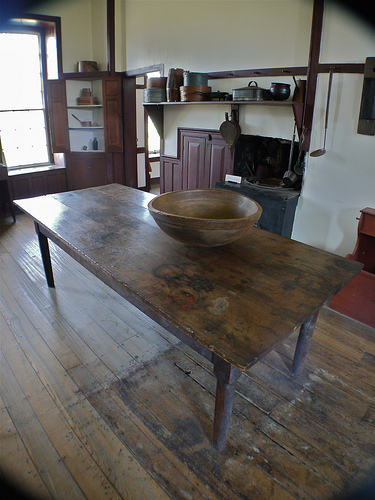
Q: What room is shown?
A: It is a kitchen.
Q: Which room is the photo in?
A: It is at the kitchen.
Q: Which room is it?
A: It is a kitchen.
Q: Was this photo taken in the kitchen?
A: Yes, it was taken in the kitchen.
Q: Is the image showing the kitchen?
A: Yes, it is showing the kitchen.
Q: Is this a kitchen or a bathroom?
A: It is a kitchen.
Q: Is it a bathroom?
A: No, it is a kitchen.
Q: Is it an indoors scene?
A: Yes, it is indoors.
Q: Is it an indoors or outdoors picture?
A: It is indoors.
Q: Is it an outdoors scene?
A: No, it is indoors.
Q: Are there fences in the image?
A: No, there are no fences.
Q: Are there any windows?
A: Yes, there is a window.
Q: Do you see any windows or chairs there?
A: Yes, there is a window.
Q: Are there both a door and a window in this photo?
A: Yes, there are both a window and a door.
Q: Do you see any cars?
A: No, there are no cars.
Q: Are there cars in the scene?
A: No, there are no cars.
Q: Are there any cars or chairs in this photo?
A: No, there are no cars or chairs.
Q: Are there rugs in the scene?
A: No, there are no rugs.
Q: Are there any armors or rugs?
A: No, there are no rugs or armors.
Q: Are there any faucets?
A: No, there are no faucets.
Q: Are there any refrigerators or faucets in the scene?
A: No, there are no faucets or refrigerators.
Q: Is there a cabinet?
A: Yes, there is a cabinet.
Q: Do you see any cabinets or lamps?
A: Yes, there is a cabinet.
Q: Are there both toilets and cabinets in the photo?
A: No, there is a cabinet but no toilets.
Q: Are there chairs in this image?
A: No, there are no chairs.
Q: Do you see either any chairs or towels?
A: No, there are no chairs or towels.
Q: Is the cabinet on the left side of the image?
A: Yes, the cabinet is on the left of the image.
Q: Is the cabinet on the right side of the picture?
A: No, the cabinet is on the left of the image.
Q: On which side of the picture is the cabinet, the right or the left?
A: The cabinet is on the left of the image.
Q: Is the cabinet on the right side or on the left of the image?
A: The cabinet is on the left of the image.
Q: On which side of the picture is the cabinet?
A: The cabinet is on the left of the image.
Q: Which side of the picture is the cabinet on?
A: The cabinet is on the left of the image.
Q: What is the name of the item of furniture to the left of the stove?
A: The piece of furniture is a cabinet.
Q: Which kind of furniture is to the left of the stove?
A: The piece of furniture is a cabinet.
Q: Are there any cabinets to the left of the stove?
A: Yes, there is a cabinet to the left of the stove.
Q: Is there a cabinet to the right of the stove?
A: No, the cabinet is to the left of the stove.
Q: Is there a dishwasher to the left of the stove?
A: No, there is a cabinet to the left of the stove.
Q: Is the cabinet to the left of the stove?
A: Yes, the cabinet is to the left of the stove.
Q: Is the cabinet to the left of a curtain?
A: No, the cabinet is to the left of the stove.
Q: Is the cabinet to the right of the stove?
A: No, the cabinet is to the left of the stove.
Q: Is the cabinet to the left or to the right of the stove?
A: The cabinet is to the left of the stove.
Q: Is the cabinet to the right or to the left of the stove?
A: The cabinet is to the left of the stove.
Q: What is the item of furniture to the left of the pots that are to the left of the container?
A: The piece of furniture is a cabinet.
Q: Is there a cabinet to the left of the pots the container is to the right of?
A: Yes, there is a cabinet to the left of the pots.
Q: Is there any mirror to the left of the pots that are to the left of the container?
A: No, there is a cabinet to the left of the pots.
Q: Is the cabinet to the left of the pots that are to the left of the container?
A: Yes, the cabinet is to the left of the pots.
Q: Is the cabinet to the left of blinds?
A: No, the cabinet is to the left of the pots.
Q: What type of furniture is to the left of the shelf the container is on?
A: The piece of furniture is a cabinet.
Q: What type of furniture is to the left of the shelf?
A: The piece of furniture is a cabinet.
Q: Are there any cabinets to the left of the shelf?
A: Yes, there is a cabinet to the left of the shelf.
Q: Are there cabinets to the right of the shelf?
A: No, the cabinet is to the left of the shelf.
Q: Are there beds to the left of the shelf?
A: No, there is a cabinet to the left of the shelf.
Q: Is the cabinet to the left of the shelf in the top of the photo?
A: Yes, the cabinet is to the left of the shelf.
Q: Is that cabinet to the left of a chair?
A: No, the cabinet is to the left of the shelf.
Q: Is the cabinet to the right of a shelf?
A: No, the cabinet is to the left of a shelf.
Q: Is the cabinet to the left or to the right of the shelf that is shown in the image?
A: The cabinet is to the left of the shelf.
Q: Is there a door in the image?
A: Yes, there are doors.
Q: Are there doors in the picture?
A: Yes, there are doors.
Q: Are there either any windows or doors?
A: Yes, there are doors.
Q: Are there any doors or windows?
A: Yes, there are doors.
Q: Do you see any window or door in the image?
A: Yes, there are doors.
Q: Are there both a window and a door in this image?
A: Yes, there are both a door and a window.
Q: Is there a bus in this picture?
A: No, there are no buses.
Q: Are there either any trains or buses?
A: No, there are no buses or trains.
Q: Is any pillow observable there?
A: No, there are no pillows.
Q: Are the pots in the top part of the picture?
A: Yes, the pots are in the top of the image.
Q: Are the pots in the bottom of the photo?
A: No, the pots are in the top of the image.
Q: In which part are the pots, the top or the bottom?
A: The pots are in the top of the image.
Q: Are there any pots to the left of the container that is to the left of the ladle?
A: Yes, there are pots to the left of the container.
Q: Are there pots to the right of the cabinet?
A: Yes, there are pots to the right of the cabinet.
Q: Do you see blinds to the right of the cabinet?
A: No, there are pots to the right of the cabinet.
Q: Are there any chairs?
A: No, there are no chairs.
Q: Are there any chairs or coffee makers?
A: No, there are no chairs or coffee makers.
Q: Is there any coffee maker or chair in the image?
A: No, there are no chairs or coffee makers.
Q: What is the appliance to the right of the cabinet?
A: The appliance is a stove.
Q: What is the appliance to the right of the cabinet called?
A: The appliance is a stove.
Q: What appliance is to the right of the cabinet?
A: The appliance is a stove.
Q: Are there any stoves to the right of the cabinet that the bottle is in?
A: Yes, there is a stove to the right of the cabinet.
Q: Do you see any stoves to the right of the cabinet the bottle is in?
A: Yes, there is a stove to the right of the cabinet.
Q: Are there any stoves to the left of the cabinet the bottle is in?
A: No, the stove is to the right of the cabinet.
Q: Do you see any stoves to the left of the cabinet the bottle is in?
A: No, the stove is to the right of the cabinet.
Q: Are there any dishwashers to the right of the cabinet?
A: No, there is a stove to the right of the cabinet.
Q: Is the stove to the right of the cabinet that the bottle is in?
A: Yes, the stove is to the right of the cabinet.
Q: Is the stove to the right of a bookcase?
A: No, the stove is to the right of the cabinet.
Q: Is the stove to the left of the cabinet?
A: No, the stove is to the right of the cabinet.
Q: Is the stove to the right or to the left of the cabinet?
A: The stove is to the right of the cabinet.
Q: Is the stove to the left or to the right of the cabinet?
A: The stove is to the right of the cabinet.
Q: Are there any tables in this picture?
A: Yes, there is a table.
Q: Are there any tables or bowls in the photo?
A: Yes, there is a table.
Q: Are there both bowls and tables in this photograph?
A: Yes, there are both a table and a bowl.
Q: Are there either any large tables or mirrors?
A: Yes, there is a large table.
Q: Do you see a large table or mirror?
A: Yes, there is a large table.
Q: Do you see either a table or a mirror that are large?
A: Yes, the table is large.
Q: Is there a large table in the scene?
A: Yes, there is a large table.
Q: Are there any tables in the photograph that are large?
A: Yes, there is a table that is large.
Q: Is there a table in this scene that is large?
A: Yes, there is a table that is large.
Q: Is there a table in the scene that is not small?
A: Yes, there is a large table.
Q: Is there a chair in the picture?
A: No, there are no chairs.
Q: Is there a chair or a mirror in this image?
A: No, there are no chairs or mirrors.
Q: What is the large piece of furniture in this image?
A: The piece of furniture is a table.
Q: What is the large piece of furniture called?
A: The piece of furniture is a table.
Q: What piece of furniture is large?
A: The piece of furniture is a table.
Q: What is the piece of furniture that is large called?
A: The piece of furniture is a table.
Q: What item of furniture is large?
A: The piece of furniture is a table.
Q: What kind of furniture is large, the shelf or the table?
A: The table is large.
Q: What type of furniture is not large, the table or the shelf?
A: The shelf is not large.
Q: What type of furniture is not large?
A: The furniture is a shelf.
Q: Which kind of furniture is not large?
A: The furniture is a shelf.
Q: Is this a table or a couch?
A: This is a table.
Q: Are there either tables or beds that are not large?
A: No, there is a table but it is large.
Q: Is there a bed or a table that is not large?
A: No, there is a table but it is large.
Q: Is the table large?
A: Yes, the table is large.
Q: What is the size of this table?
A: The table is large.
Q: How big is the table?
A: The table is large.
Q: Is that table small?
A: No, the table is large.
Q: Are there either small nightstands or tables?
A: No, there is a table but it is large.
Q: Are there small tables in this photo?
A: No, there is a table but it is large.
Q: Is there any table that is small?
A: No, there is a table but it is large.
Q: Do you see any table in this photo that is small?
A: No, there is a table but it is large.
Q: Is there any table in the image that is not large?
A: No, there is a table but it is large.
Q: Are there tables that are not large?
A: No, there is a table but it is large.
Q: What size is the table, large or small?
A: The table is large.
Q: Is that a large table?
A: Yes, that is a large table.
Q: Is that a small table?
A: No, that is a large table.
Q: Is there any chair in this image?
A: No, there are no chairs.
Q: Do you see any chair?
A: No, there are no chairs.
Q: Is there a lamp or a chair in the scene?
A: No, there are no chairs or lamps.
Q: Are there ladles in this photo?
A: Yes, there is a ladle.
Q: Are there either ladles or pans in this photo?
A: Yes, there is a ladle.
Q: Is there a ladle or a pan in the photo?
A: Yes, there is a ladle.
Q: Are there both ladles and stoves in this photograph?
A: Yes, there are both a ladle and a stove.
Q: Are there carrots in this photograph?
A: No, there are no carrots.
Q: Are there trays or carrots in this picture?
A: No, there are no carrots or trays.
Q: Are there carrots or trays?
A: No, there are no carrots or trays.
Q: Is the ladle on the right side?
A: Yes, the ladle is on the right of the image.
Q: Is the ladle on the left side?
A: No, the ladle is on the right of the image.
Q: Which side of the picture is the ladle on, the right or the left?
A: The ladle is on the right of the image.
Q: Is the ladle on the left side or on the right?
A: The ladle is on the right of the image.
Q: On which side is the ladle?
A: The ladle is on the right of the image.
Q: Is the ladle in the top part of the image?
A: Yes, the ladle is in the top of the image.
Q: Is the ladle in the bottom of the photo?
A: No, the ladle is in the top of the image.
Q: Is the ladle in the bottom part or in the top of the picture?
A: The ladle is in the top of the image.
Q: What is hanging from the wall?
A: The ladle is hanging from the wall.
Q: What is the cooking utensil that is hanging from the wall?
A: The cooking utensil is a ladle.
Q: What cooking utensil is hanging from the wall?
A: The cooking utensil is a ladle.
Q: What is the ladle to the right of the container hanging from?
A: The ladle is hanging from the wall.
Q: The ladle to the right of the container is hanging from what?
A: The ladle is hanging from the wall.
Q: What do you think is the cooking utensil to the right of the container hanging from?
A: The ladle is hanging from the wall.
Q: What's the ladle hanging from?
A: The ladle is hanging from the wall.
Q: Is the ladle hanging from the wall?
A: Yes, the ladle is hanging from the wall.